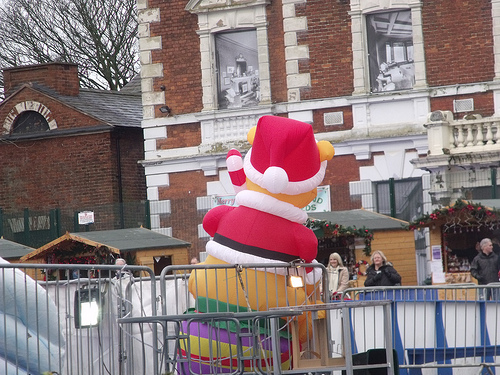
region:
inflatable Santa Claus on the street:
[179, 111, 336, 373]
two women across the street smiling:
[325, 247, 404, 299]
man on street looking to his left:
[468, 235, 498, 285]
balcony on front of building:
[407, 108, 497, 189]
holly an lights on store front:
[409, 198, 498, 236]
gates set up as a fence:
[0, 257, 495, 369]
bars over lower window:
[371, 175, 421, 220]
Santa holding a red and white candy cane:
[221, 145, 241, 190]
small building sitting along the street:
[2, 205, 412, 285]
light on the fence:
[3, 207, 420, 284]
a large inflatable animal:
[172, 109, 342, 371]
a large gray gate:
[149, 253, 351, 373]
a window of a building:
[363, 9, 418, 101]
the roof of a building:
[48, 78, 140, 126]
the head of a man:
[479, 238, 494, 254]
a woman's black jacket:
[366, 262, 401, 286]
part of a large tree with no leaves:
[1, 0, 145, 87]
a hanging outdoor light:
[284, 265, 305, 290]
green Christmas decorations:
[311, 217, 375, 257]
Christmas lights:
[439, 215, 494, 232]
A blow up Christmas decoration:
[178, 108, 323, 374]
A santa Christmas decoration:
[185, 90, 333, 374]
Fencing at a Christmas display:
[2, 251, 496, 367]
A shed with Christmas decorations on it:
[416, 186, 498, 293]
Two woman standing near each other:
[323, 243, 405, 287]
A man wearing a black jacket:
[463, 227, 498, 287]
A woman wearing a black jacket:
[360, 243, 403, 286]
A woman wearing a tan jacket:
[316, 245, 348, 301]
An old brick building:
[3, 60, 127, 229]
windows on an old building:
[187, 4, 455, 100]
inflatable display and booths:
[3, 3, 493, 369]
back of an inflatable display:
[172, 111, 340, 370]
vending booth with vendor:
[413, 193, 497, 303]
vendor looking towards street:
[465, 235, 497, 302]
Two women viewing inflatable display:
[321, 248, 406, 296]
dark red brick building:
[3, 61, 136, 247]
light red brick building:
[127, 2, 498, 269]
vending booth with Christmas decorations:
[412, 195, 479, 297]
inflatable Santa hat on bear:
[240, 109, 329, 196]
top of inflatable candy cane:
[221, 145, 247, 195]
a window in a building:
[209, 21, 268, 116]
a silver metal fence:
[265, 285, 468, 366]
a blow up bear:
[186, 108, 343, 352]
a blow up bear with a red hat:
[196, 108, 352, 271]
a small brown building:
[28, 208, 192, 288]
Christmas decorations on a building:
[427, 198, 499, 242]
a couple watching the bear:
[319, 243, 404, 298]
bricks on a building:
[38, 116, 142, 196]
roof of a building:
[5, 60, 143, 117]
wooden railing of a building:
[420, 108, 499, 168]